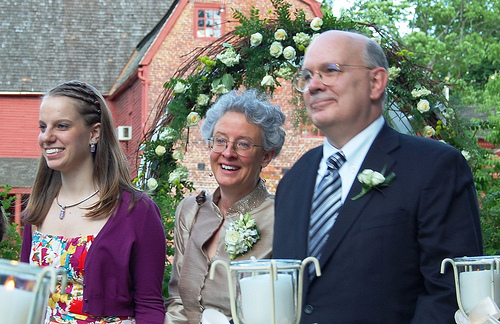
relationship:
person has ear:
[22, 69, 170, 314] [86, 120, 106, 147]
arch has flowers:
[136, 12, 483, 194] [247, 17, 325, 85]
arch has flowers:
[136, 12, 483, 194] [215, 44, 244, 69]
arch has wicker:
[136, 12, 483, 194] [138, 13, 282, 172]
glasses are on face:
[292, 63, 346, 90] [299, 32, 371, 126]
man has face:
[269, 28, 483, 322] [299, 32, 371, 126]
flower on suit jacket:
[342, 167, 404, 207] [269, 129, 424, 319]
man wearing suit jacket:
[269, 28, 483, 322] [269, 129, 424, 319]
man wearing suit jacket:
[269, 28, 483, 322] [269, 117, 476, 322]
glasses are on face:
[209, 135, 266, 155] [210, 111, 264, 183]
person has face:
[161, 89, 286, 324] [210, 111, 264, 183]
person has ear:
[18, 79, 168, 324] [90, 117, 103, 157]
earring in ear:
[86, 141, 103, 158] [90, 117, 103, 157]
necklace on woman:
[48, 184, 108, 221] [17, 80, 167, 322]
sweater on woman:
[14, 180, 163, 322] [17, 80, 167, 322]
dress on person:
[28, 223, 95, 322] [18, 79, 168, 324]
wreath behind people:
[145, 12, 435, 123] [16, 40, 453, 281]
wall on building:
[81, 46, 261, 156] [5, 0, 352, 140]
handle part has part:
[260, 255, 280, 289] [271, 258, 278, 272]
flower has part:
[349, 167, 394, 202] [363, 170, 372, 180]